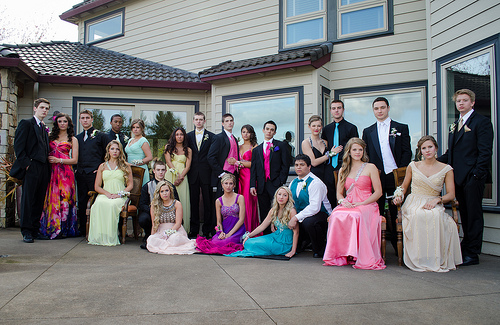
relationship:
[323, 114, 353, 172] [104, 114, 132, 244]
blue tie on black man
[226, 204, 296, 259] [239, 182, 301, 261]
dress on girl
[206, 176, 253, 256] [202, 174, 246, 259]
dress on girl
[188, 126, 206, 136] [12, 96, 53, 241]
tie on man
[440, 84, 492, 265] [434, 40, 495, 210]
boy standing by window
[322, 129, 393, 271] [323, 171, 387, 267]
girl wears dress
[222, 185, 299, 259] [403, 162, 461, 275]
girl wears dress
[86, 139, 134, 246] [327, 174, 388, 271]
girl wears dress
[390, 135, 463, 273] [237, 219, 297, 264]
girl wears dress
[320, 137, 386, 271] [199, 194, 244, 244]
girl wears dress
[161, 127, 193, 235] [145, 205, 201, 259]
girl wears dress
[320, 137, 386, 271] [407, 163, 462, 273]
girl wears dress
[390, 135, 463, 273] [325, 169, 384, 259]
girl wears dress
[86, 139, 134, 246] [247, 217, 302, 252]
girl wears dress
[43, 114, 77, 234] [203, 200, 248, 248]
girl wears dress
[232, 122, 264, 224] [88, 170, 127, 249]
girl wears dress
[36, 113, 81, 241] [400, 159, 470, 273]
girl wears dress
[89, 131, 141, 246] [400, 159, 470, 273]
girl wears dress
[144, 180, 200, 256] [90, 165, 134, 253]
girl wears dress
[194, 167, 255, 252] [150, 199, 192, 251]
girl wears dress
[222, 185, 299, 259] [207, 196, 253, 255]
girl wears dress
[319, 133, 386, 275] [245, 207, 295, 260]
girl wears dress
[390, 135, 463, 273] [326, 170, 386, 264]
girl wears dress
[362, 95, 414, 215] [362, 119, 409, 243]
man wears tuxedo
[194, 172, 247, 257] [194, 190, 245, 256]
girl wears dress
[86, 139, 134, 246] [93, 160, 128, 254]
girl wears dress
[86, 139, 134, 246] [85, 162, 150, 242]
girl sitting in chair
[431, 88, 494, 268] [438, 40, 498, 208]
boy standing next to window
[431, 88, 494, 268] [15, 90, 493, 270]
boy at edge of group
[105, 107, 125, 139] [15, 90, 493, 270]
black man standing with group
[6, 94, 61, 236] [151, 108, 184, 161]
man in front of plant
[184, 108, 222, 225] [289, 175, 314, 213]
man in blue vest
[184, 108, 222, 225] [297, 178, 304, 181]
man in blue tie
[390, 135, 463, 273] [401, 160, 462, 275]
girl wearing gown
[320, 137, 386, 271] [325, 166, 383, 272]
girl wearing gown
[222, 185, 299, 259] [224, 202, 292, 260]
girl wearing gown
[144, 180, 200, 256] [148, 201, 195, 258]
girl wearing gown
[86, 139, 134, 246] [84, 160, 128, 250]
girl wearing gown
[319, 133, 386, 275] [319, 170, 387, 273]
girl wearing gown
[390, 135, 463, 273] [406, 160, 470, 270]
girl wearing gown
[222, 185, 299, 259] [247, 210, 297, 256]
girl wearing gown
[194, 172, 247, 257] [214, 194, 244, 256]
girl wearing gown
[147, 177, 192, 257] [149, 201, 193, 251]
girl wearing gown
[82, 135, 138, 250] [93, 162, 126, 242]
girl wearing gown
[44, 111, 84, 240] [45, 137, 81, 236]
girl wearing gown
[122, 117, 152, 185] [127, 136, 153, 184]
girl wearing gown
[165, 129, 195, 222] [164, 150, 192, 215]
girl wearing gown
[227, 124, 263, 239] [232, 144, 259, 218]
girl wearing gown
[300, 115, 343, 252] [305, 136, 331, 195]
girl wearing gown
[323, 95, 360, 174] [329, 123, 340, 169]
man wearing blue tie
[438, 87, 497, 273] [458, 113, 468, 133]
man wearing tie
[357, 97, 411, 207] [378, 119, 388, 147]
man wearing tie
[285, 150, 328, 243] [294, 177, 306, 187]
man wearing tie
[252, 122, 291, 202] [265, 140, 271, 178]
man wearing tie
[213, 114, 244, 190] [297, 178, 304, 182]
man wearing blue tie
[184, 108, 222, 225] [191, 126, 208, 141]
man wearing tie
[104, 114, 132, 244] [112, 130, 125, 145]
black man wearing tie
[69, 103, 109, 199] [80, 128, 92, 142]
man wearing tie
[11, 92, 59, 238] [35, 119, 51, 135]
man wearing tie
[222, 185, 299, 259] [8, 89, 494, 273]
girl in party